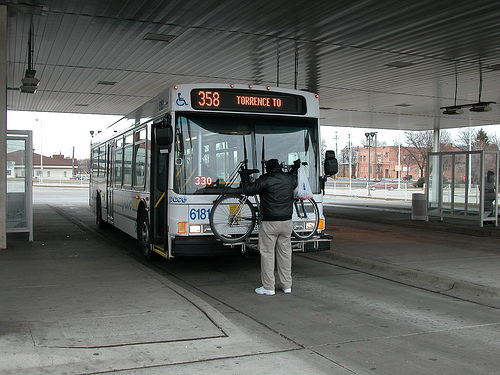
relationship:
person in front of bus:
[239, 159, 300, 295] [91, 82, 330, 262]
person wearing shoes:
[239, 159, 300, 295] [254, 285, 291, 295]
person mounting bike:
[239, 159, 300, 295] [210, 161, 319, 243]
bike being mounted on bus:
[210, 161, 319, 243] [91, 82, 330, 262]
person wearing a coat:
[239, 159, 300, 295] [240, 166, 298, 222]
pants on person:
[258, 220, 294, 291] [239, 159, 300, 295]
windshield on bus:
[172, 110, 320, 195] [91, 82, 330, 262]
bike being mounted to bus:
[210, 161, 319, 243] [91, 82, 330, 262]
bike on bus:
[210, 161, 319, 243] [91, 82, 330, 262]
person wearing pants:
[239, 159, 300, 295] [258, 220, 294, 291]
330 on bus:
[194, 176, 212, 186] [91, 82, 330, 262]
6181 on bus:
[190, 208, 210, 221] [91, 82, 330, 262]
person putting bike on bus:
[239, 159, 300, 295] [91, 82, 330, 262]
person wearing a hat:
[239, 159, 300, 295] [265, 158, 280, 171]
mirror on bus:
[321, 149, 338, 183] [91, 82, 330, 262]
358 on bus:
[198, 90, 218, 107] [91, 82, 330, 262]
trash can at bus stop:
[411, 193, 428, 220] [0, 1, 499, 374]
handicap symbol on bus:
[176, 92, 189, 107] [91, 82, 330, 262]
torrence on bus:
[236, 94, 270, 107] [91, 82, 330, 262]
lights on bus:
[177, 219, 323, 234] [91, 82, 330, 262]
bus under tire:
[91, 82, 330, 262] [137, 207, 162, 260]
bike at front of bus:
[210, 161, 319, 243] [91, 82, 330, 262]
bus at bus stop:
[91, 82, 330, 262] [0, 1, 499, 374]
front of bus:
[169, 80, 326, 256] [91, 82, 330, 262]